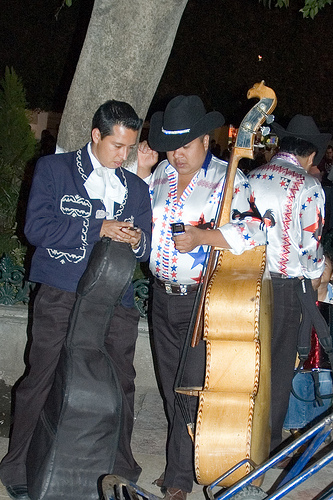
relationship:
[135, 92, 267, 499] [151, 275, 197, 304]
man wearing belt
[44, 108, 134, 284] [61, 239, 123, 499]
man holding case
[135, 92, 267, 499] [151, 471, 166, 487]
man wearing shoe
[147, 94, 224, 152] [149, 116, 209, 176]
black hat on head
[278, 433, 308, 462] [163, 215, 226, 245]
pipe lost paint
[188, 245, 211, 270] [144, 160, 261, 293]
star on shirt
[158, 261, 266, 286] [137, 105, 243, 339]
belt on man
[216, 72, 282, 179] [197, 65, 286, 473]
handle of cello